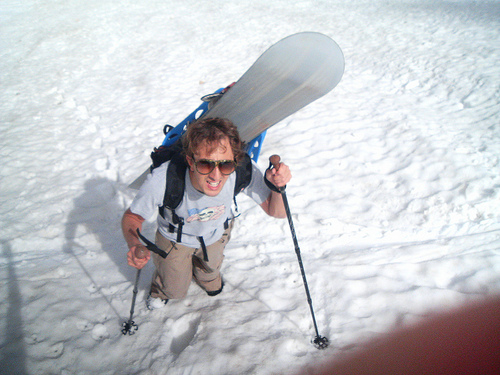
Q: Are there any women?
A: No, there are no women.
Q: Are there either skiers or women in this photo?
A: No, there are no women or skiers.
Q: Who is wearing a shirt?
A: The man is wearing a shirt.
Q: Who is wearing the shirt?
A: The man is wearing a shirt.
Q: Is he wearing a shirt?
A: Yes, the man is wearing a shirt.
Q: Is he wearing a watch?
A: No, the man is wearing a shirt.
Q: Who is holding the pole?
A: The man is holding the pole.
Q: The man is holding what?
A: The man is holding the pole.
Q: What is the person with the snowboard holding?
A: The man is holding the pole.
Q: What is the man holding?
A: The man is holding the pole.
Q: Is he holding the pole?
A: Yes, the man is holding the pole.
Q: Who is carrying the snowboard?
A: The man is carrying the snowboard.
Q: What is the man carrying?
A: The man is carrying a snowboard.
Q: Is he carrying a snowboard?
A: Yes, the man is carrying a snowboard.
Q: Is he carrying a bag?
A: No, the man is carrying a snowboard.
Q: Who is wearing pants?
A: The man is wearing pants.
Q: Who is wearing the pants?
A: The man is wearing pants.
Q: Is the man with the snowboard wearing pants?
A: Yes, the man is wearing pants.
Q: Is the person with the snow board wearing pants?
A: Yes, the man is wearing pants.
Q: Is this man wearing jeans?
A: No, the man is wearing pants.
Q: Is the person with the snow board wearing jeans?
A: No, the man is wearing pants.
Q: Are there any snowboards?
A: Yes, there is a snowboard.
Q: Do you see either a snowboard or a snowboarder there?
A: Yes, there is a snowboard.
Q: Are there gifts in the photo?
A: No, there are no gifts.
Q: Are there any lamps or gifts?
A: No, there are no gifts or lamps.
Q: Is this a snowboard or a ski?
A: This is a snowboard.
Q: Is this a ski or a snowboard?
A: This is a snowboard.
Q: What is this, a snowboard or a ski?
A: This is a snowboard.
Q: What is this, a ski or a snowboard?
A: This is a snowboard.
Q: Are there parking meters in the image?
A: No, there are no parking meters.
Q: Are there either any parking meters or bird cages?
A: No, there are no parking meters or bird cages.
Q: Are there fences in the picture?
A: No, there are no fences.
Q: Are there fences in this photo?
A: No, there are no fences.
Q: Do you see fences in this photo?
A: No, there are no fences.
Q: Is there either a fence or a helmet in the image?
A: No, there are no fences or helmets.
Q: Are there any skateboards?
A: No, there are no skateboards.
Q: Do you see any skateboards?
A: No, there are no skateboards.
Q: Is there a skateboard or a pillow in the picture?
A: No, there are no skateboards or pillows.